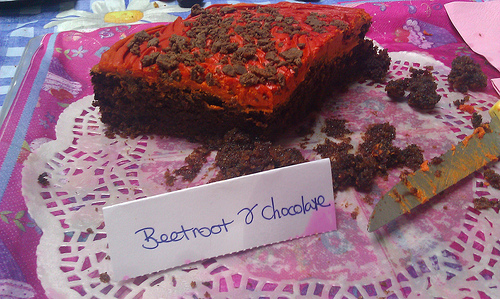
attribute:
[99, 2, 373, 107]
frosting — orange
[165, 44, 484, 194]
crumbs — cake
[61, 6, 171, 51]
daisy — white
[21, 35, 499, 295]
doyle — white, paper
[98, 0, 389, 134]
cake — beetroot, chocolate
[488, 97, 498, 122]
handle — yellow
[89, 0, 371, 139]
cake —  brown and red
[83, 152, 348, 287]
paper — white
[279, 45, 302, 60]
chunk — chocolate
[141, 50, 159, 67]
chunk — chocolate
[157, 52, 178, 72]
chunk — chocolate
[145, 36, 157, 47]
chunk — chocolate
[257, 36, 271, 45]
chunk — chocolate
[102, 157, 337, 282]
paper — white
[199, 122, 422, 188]
crumbs — brown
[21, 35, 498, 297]
doily — white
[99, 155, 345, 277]
sign —  white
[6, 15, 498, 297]
tray — pink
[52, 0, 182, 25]
flower — white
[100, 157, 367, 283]
label — white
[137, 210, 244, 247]
inkprint — blue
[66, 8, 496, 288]
chocolate cake — frosted, red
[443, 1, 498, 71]
napkin — pink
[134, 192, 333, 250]
writing —  blue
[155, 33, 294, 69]
bits — chocolate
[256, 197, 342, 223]
inkprint — blue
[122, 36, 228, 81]
topping — chocolate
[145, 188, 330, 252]
writing — blue